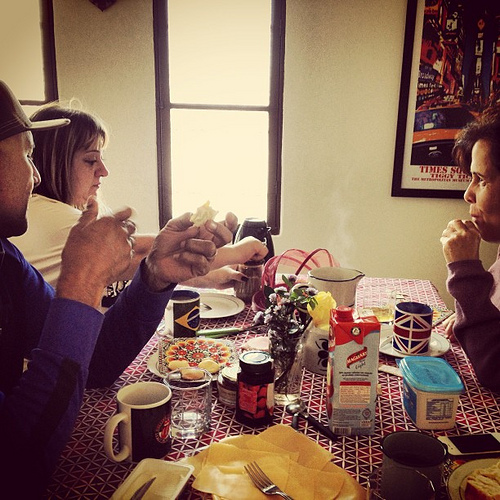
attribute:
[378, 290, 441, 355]
mug — british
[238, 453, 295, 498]
fork table — silver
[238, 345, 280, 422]
jelly jar — with  jelly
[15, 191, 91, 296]
shirt — white